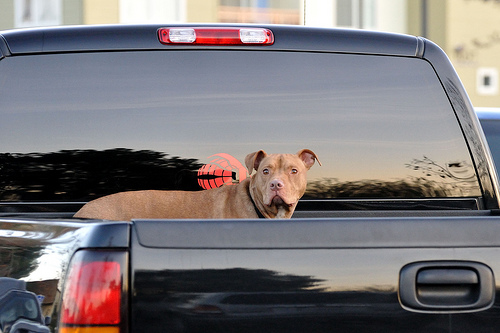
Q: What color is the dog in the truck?
A: Brown.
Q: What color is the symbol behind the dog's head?
A: Red.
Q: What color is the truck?
A: Black.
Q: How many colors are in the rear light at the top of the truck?
A: Two.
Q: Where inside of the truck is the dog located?
A: The back.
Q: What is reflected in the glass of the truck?
A: Trees.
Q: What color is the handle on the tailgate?
A: Black.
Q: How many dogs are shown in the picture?
A: One.